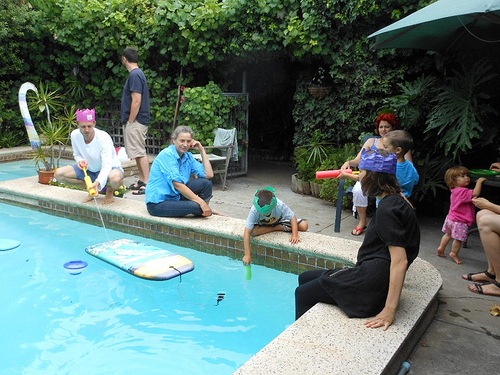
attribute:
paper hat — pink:
[71, 105, 97, 123]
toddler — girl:
[435, 162, 484, 263]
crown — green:
[254, 187, 275, 212]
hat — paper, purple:
[344, 147, 424, 182]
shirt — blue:
[145, 155, 179, 204]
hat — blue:
[354, 141, 395, 169]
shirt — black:
[318, 191, 421, 317]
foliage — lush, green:
[47, 14, 319, 146]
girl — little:
[436, 181, 496, 245]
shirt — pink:
[446, 186, 484, 223]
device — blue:
[63, 257, 89, 275]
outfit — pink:
[433, 186, 476, 242]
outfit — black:
[291, 190, 422, 320]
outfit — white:
[68, 127, 125, 188]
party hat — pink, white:
[71, 106, 99, 123]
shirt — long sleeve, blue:
[143, 144, 205, 204]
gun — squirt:
[81, 160, 98, 202]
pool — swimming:
[1, 144, 441, 373]